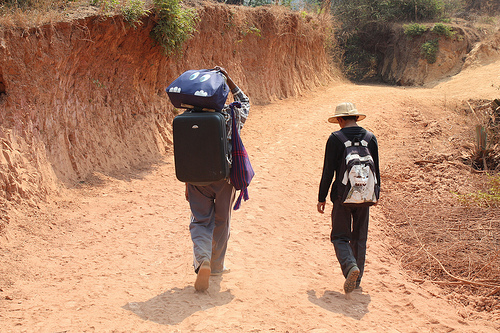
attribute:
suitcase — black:
[173, 115, 229, 180]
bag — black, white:
[334, 129, 379, 209]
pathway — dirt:
[21, 77, 400, 332]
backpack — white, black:
[325, 125, 381, 216]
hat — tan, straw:
[325, 102, 365, 129]